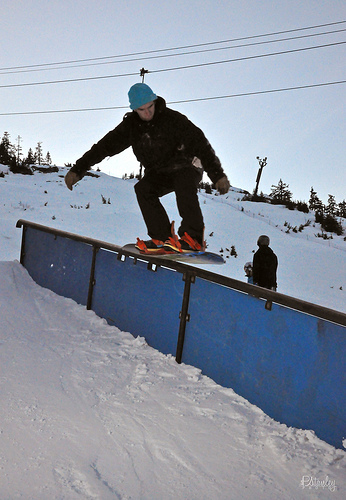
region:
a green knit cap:
[126, 82, 154, 109]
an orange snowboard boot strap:
[132, 218, 178, 251]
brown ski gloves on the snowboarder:
[62, 165, 80, 187]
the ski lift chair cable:
[0, 15, 343, 79]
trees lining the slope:
[232, 152, 341, 229]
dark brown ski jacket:
[69, 119, 231, 182]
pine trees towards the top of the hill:
[0, 130, 63, 174]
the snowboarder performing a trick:
[64, 83, 228, 267]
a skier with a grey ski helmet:
[242, 260, 253, 272]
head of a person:
[118, 76, 169, 123]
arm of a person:
[82, 133, 126, 182]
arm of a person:
[171, 114, 231, 172]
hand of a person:
[66, 163, 93, 187]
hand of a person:
[209, 171, 252, 195]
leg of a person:
[135, 183, 170, 231]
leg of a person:
[175, 175, 226, 232]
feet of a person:
[126, 235, 165, 257]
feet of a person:
[156, 232, 219, 276]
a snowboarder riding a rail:
[16, 55, 293, 284]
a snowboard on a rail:
[118, 231, 232, 281]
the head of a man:
[122, 82, 165, 126]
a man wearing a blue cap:
[124, 79, 166, 127]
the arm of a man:
[187, 124, 234, 194]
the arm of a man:
[63, 129, 130, 196]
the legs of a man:
[137, 174, 217, 251]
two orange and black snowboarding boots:
[133, 233, 206, 258]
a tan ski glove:
[209, 171, 234, 199]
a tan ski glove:
[56, 164, 90, 195]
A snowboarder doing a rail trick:
[56, 77, 242, 272]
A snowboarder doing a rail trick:
[56, 79, 234, 268]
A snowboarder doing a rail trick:
[57, 78, 238, 266]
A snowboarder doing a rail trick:
[56, 79, 233, 264]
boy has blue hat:
[115, 88, 162, 115]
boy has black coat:
[106, 117, 218, 196]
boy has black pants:
[128, 156, 203, 232]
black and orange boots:
[132, 227, 192, 247]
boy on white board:
[119, 232, 221, 270]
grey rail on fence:
[29, 218, 342, 337]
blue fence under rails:
[14, 228, 332, 401]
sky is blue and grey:
[155, 8, 288, 118]